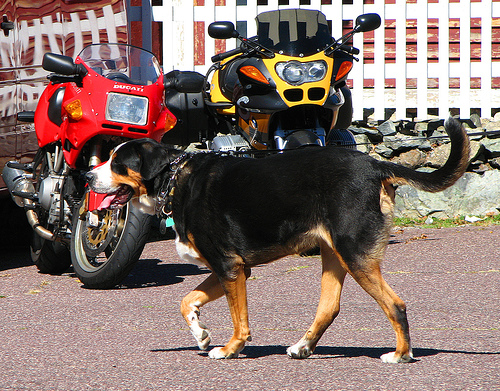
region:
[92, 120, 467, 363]
dog is black and brown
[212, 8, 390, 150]
bike is behind the dog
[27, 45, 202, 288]
bike is behind the dog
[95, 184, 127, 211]
dog has tongue out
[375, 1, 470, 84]
fence is white in color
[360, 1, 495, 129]
fence is behind the bikes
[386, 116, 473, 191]
dog has a long tail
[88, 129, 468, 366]
dog is on the street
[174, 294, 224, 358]
dog's leg is up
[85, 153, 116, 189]
white spot on dog's face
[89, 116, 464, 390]
Dog walkimg on pavement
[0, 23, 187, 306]
Motorcycle parked on pavement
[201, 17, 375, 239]
Motorcycle parked on pavement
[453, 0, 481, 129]
White wooden fence post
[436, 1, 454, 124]
White wooden fence post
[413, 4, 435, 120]
White wooden fence post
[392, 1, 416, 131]
White wooden fence post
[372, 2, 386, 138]
White wooden fence post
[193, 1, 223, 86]
White wooden fence post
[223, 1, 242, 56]
White wooden fence post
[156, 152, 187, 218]
The collar on the dog.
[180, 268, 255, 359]
The front legs of the dog.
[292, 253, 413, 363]
The back legs of the dog.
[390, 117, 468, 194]
The tail of the dog.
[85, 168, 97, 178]
The nose of the dog.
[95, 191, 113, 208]
The tongue of the dog.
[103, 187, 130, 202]
The mouth of the dog.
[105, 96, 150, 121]
The front headlight on the red motorcycle.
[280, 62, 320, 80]
The headlight on the yellow motorcycle.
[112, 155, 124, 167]
The eye of the dog.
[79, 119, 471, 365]
shiny dog walking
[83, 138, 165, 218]
tongue hanging out of a dogs mouth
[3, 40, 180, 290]
red parked motorcycle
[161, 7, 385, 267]
big yellow and black mortorcycle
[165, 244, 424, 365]
four brown dog legs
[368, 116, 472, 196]
black and brown dog tail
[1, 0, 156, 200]
reflections on a shiny surface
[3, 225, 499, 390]
gray paved ground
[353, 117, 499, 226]
piled up rock wall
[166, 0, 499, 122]
white slated fencing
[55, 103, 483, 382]
dog walking on the street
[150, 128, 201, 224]
collar and bandana on a dog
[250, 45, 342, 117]
yellow front of a motorcycle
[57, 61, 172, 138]
red front of a motorcycle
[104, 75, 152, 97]
ducati written in white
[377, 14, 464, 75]
many white slats on a fence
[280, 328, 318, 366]
white paw on a dog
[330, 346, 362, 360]
shadow from a dog on the ground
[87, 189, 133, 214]
tongue out of the mouth of a dog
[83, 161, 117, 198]
white snout on a dog